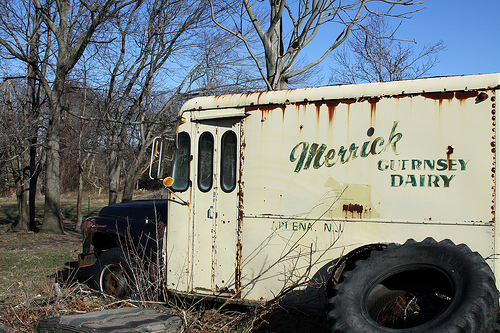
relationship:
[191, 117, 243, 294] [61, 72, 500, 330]
door leading to dairy truck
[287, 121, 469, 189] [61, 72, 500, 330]
green logo painted on dairy truck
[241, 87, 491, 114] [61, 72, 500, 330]
rust formed on dairy truck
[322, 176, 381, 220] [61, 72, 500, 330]
cow shape faded on dairy truck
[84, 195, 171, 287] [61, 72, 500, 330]
paint painted on dairy truck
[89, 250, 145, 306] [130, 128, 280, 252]
tire mounted on truck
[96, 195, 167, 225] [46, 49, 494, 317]
hood mounted on truck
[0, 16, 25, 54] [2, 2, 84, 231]
branch growing on tree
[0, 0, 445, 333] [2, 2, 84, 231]
branch growing on tree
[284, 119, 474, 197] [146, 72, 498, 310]
green logo on truck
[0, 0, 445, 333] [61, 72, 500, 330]
branch beside dairy truck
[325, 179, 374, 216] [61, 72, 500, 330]
cow shape on dairy truck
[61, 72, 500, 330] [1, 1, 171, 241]
dairy truck in wooded area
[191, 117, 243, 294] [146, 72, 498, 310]
door on truck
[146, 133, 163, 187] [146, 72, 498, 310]
mirror on truck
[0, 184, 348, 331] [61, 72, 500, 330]
weeds by dairy truck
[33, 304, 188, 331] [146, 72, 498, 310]
rock by truck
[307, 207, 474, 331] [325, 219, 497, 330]
tire leaning truck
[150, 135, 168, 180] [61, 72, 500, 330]
mirror are on dairy truck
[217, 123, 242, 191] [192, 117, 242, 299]
window in door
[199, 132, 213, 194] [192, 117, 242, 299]
window in door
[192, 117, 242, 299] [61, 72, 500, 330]
door in dairy truck